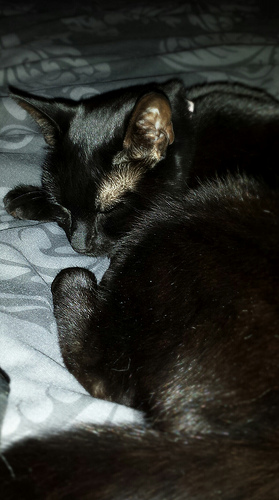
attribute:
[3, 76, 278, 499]
cat — sleeping, black, resting, furry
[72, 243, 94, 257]
nose — black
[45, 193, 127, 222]
eyes — closed, shut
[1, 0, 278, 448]
blanket — gray, dark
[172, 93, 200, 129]
collar — white